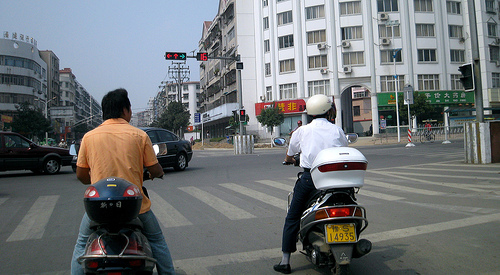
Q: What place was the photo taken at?
A: It was taken at the road.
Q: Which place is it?
A: It is a road.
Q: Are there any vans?
A: No, there are no vans.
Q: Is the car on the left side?
A: Yes, the car is on the left of the image.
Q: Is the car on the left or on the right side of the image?
A: The car is on the left of the image.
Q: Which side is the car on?
A: The car is on the left of the image.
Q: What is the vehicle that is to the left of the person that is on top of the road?
A: The vehicle is a car.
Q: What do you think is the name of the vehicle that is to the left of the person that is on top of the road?
A: The vehicle is a car.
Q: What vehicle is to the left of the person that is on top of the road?
A: The vehicle is a car.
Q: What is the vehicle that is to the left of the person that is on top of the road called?
A: The vehicle is a car.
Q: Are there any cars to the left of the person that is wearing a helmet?
A: Yes, there is a car to the left of the person.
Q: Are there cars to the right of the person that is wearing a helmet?
A: No, the car is to the left of the person.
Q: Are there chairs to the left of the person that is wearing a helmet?
A: No, there is a car to the left of the person.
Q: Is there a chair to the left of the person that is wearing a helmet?
A: No, there is a car to the left of the person.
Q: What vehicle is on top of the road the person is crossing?
A: The vehicle is a car.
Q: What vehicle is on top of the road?
A: The vehicle is a car.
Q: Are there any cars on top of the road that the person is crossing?
A: Yes, there is a car on top of the road.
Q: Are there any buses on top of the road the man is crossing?
A: No, there is a car on top of the road.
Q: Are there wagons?
A: No, there are no wagons.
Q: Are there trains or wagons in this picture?
A: No, there are no wagons or trains.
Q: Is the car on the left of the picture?
A: Yes, the car is on the left of the image.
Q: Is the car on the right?
A: No, the car is on the left of the image.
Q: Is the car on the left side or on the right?
A: The car is on the left of the image.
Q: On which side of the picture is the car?
A: The car is on the left of the image.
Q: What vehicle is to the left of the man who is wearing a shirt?
A: The vehicle is a car.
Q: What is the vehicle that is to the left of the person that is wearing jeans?
A: The vehicle is a car.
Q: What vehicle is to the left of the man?
A: The vehicle is a car.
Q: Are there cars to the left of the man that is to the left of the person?
A: Yes, there is a car to the left of the man.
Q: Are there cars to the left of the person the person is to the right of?
A: Yes, there is a car to the left of the man.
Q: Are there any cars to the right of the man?
A: No, the car is to the left of the man.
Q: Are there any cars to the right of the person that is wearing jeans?
A: No, the car is to the left of the man.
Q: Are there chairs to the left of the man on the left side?
A: No, there is a car to the left of the man.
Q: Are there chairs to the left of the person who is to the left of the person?
A: No, there is a car to the left of the man.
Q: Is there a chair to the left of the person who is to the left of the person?
A: No, there is a car to the left of the man.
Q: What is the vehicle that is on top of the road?
A: The vehicle is a car.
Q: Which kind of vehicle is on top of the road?
A: The vehicle is a car.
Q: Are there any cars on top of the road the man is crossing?
A: Yes, there is a car on top of the road.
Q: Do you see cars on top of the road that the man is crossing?
A: Yes, there is a car on top of the road.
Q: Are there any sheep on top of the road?
A: No, there is a car on top of the road.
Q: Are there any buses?
A: No, there are no buses.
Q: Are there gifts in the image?
A: No, there are no gifts.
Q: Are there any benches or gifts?
A: No, there are no gifts or benches.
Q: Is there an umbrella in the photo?
A: No, there are no umbrellas.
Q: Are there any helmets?
A: Yes, there is a helmet.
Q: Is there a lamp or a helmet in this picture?
A: Yes, there is a helmet.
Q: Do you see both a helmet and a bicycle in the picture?
A: No, there is a helmet but no bicycles.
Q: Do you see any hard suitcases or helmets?
A: Yes, there is a hard helmet.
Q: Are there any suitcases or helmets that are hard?
A: Yes, the helmet is hard.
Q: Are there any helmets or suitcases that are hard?
A: Yes, the helmet is hard.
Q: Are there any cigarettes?
A: No, there are no cigarettes.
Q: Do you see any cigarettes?
A: No, there are no cigarettes.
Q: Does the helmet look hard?
A: Yes, the helmet is hard.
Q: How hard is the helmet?
A: The helmet is hard.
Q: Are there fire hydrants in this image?
A: No, there are no fire hydrants.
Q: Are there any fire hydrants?
A: No, there are no fire hydrants.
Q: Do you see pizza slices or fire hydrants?
A: No, there are no fire hydrants or pizza slices.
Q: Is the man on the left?
A: Yes, the man is on the left of the image.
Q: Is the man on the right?
A: No, the man is on the left of the image.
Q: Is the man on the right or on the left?
A: The man is on the left of the image.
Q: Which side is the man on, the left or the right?
A: The man is on the left of the image.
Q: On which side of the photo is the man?
A: The man is on the left of the image.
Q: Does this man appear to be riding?
A: Yes, the man is riding.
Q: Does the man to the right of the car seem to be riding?
A: Yes, the man is riding.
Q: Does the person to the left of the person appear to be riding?
A: Yes, the man is riding.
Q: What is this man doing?
A: The man is riding.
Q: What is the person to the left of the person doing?
A: The man is riding.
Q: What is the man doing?
A: The man is riding.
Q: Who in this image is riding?
A: The man is riding.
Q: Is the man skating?
A: No, the man is riding.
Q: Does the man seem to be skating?
A: No, the man is riding.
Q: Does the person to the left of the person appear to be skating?
A: No, the man is riding.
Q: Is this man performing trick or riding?
A: The man is riding.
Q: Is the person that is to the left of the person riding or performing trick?
A: The man is riding.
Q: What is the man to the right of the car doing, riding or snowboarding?
A: The man is riding.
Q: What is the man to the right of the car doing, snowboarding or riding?
A: The man is riding.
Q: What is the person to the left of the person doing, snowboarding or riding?
A: The man is riding.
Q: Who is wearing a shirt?
A: The man is wearing a shirt.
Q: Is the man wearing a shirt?
A: Yes, the man is wearing a shirt.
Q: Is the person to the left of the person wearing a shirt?
A: Yes, the man is wearing a shirt.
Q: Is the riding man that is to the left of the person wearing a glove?
A: No, the man is wearing a shirt.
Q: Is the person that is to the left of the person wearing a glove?
A: No, the man is wearing a shirt.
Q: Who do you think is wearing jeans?
A: The man is wearing jeans.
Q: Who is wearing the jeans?
A: The man is wearing jeans.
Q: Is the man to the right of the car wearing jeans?
A: Yes, the man is wearing jeans.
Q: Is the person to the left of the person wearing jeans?
A: Yes, the man is wearing jeans.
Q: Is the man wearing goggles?
A: No, the man is wearing jeans.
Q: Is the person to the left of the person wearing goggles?
A: No, the man is wearing jeans.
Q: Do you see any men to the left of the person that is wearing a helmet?
A: Yes, there is a man to the left of the person.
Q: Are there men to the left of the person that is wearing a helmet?
A: Yes, there is a man to the left of the person.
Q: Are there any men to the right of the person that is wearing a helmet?
A: No, the man is to the left of the person.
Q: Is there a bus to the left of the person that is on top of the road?
A: No, there is a man to the left of the person.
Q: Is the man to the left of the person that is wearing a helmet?
A: Yes, the man is to the left of the person.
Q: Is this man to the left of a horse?
A: No, the man is to the left of the person.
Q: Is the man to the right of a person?
A: No, the man is to the left of a person.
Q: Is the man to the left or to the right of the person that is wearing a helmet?
A: The man is to the left of the person.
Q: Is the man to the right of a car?
A: Yes, the man is to the right of a car.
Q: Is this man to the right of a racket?
A: No, the man is to the right of a car.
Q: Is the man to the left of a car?
A: No, the man is to the right of a car.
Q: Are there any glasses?
A: No, there are no glasses.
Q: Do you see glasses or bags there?
A: No, there are no glasses or bags.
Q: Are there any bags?
A: No, there are no bags.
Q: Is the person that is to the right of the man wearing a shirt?
A: Yes, the person is wearing a shirt.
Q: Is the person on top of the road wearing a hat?
A: No, the person is wearing a shirt.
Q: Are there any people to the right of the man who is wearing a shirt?
A: Yes, there is a person to the right of the man.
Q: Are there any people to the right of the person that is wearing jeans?
A: Yes, there is a person to the right of the man.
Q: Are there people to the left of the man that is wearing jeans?
A: No, the person is to the right of the man.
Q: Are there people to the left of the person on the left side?
A: No, the person is to the right of the man.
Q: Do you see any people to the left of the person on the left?
A: No, the person is to the right of the man.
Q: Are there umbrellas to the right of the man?
A: No, there is a person to the right of the man.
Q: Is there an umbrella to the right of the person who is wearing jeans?
A: No, there is a person to the right of the man.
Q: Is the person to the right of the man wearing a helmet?
A: Yes, the person is wearing a helmet.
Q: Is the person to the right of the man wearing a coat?
A: No, the person is wearing a helmet.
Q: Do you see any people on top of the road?
A: Yes, there is a person on top of the road.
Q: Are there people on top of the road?
A: Yes, there is a person on top of the road.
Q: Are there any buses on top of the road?
A: No, there is a person on top of the road.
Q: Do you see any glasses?
A: No, there are no glasses.